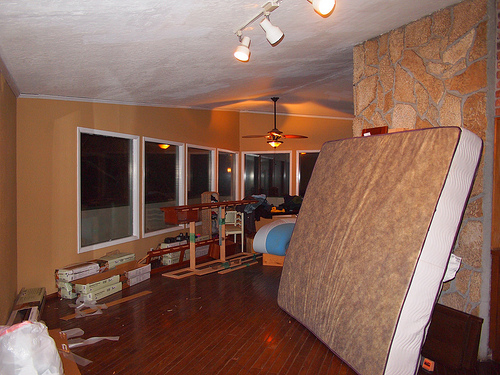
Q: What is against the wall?
A: Bed.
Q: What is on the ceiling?
A: Lights.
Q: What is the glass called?
A: Window.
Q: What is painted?
A: The wall.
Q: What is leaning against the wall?
A: Mattress.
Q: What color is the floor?
A: Brown.